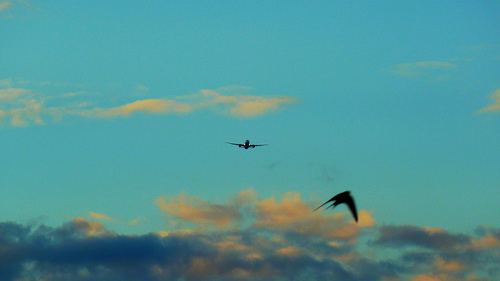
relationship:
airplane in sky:
[222, 138, 268, 150] [2, 0, 499, 232]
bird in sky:
[310, 189, 357, 223] [2, 0, 499, 232]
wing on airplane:
[253, 143, 269, 148] [222, 138, 268, 150]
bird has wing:
[310, 189, 357, 223] [340, 195, 365, 224]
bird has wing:
[310, 189, 357, 223] [308, 195, 335, 212]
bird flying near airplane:
[310, 189, 357, 223] [222, 138, 268, 150]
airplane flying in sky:
[222, 136, 265, 155] [17, 13, 478, 261]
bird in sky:
[310, 189, 357, 223] [2, 1, 499, 279]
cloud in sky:
[2, 186, 497, 278] [2, 1, 499, 279]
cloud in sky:
[5, 80, 298, 123] [2, 1, 499, 279]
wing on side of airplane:
[223, 141, 242, 148] [222, 138, 268, 150]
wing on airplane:
[253, 138, 267, 150] [222, 138, 268, 150]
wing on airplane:
[226, 138, 242, 150] [222, 138, 268, 150]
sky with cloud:
[2, 1, 499, 279] [2, 186, 497, 278]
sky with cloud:
[2, 1, 499, 279] [5, 80, 298, 123]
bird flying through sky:
[317, 189, 358, 223] [2, 1, 499, 279]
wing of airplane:
[253, 143, 269, 148] [222, 136, 270, 151]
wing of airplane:
[223, 141, 242, 148] [222, 136, 270, 151]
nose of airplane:
[237, 129, 265, 151] [228, 133, 266, 160]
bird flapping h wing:
[310, 189, 357, 223] [340, 195, 365, 224]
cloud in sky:
[2, 213, 497, 278] [2, 1, 499, 279]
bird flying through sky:
[310, 189, 357, 223] [2, 1, 499, 279]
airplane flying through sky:
[222, 138, 268, 150] [2, 1, 499, 279]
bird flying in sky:
[317, 189, 358, 223] [2, 1, 499, 279]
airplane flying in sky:
[222, 138, 268, 150] [2, 1, 499, 279]